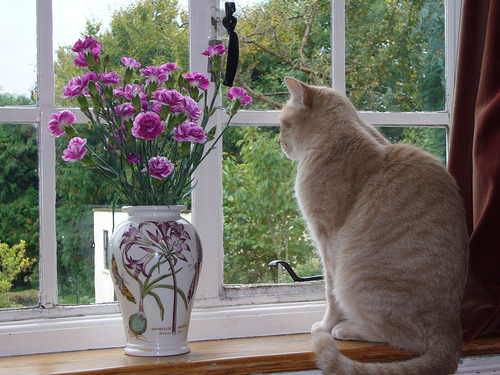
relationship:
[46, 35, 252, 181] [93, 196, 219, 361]
flowers in vase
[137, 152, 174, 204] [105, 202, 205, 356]
purple flower in vase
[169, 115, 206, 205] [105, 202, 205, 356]
purple flower in vase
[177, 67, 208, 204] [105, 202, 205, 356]
purple flower in vase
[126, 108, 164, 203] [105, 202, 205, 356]
purple flower in vase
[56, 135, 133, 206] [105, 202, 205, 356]
purple flower in vase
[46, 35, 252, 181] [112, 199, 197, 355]
flowers in vase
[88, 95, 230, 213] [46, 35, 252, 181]
stems of flowers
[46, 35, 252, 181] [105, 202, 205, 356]
flowers in vase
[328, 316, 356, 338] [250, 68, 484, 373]
foot of cat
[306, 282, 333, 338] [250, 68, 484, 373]
front foot of cat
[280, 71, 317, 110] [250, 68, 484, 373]
ear of cat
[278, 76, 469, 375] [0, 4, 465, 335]
cat looking out of window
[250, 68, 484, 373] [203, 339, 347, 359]
cat on sill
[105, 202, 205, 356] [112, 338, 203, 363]
vase on window sill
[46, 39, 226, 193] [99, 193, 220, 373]
flowers in vase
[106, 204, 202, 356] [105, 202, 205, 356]
flowers on vase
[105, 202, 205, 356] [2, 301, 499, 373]
vase on windowsill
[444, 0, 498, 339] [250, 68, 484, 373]
curtain beside cat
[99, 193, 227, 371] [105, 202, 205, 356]
flowers painted on vase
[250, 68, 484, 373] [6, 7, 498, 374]
cat looking out window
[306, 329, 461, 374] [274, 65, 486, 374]
tail of cat